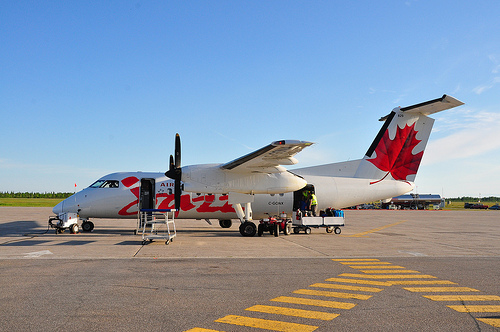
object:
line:
[446, 304, 499, 313]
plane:
[51, 93, 465, 237]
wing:
[218, 139, 314, 175]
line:
[243, 303, 338, 320]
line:
[473, 316, 500, 328]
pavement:
[0, 206, 500, 331]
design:
[366, 120, 423, 187]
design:
[117, 174, 246, 219]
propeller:
[163, 131, 182, 210]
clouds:
[472, 82, 492, 97]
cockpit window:
[100, 179, 121, 187]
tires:
[82, 220, 94, 232]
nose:
[51, 200, 68, 215]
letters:
[217, 194, 247, 212]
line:
[270, 295, 358, 309]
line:
[215, 312, 319, 331]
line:
[387, 279, 461, 285]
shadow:
[0, 220, 292, 238]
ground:
[0, 204, 500, 331]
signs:
[330, 257, 381, 262]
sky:
[0, 0, 500, 198]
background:
[0, 0, 500, 331]